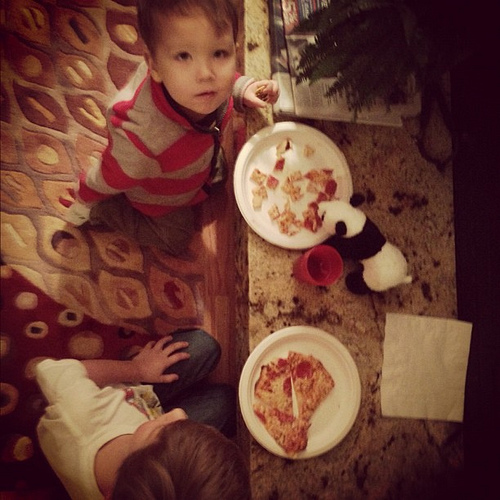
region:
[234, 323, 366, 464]
Pizza on a plate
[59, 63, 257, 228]
A sweater is gray and red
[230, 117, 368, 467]
Two plates on a table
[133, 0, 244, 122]
Brown hair on boy's head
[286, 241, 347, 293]
Red cup on the table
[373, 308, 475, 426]
A napkin is square shaped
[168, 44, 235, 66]
A pair of eyes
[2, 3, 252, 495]
Two boys are sitting on a rug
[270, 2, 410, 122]
newspapers on the counter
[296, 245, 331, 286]
a red cup on the counter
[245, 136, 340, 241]
a plate of food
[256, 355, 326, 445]
pizza on a plate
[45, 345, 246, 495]
a boy with a white shirt on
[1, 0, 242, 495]
the red carpet under the boys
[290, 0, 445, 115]
a plant on the counter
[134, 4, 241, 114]
a boy with brown light hair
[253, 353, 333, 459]
pizza slices in a white plate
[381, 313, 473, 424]
a white sheet of paper towel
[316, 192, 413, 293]
a panda plushie eating bits of pizza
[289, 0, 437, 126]
green leaves of a plant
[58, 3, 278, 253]
a boy sitting on a carpet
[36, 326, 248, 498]
a girl sitting on a carpet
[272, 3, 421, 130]
folded newspapers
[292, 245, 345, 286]
a red plastic glass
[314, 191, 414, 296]
a black and white panda plushie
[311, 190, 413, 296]
a small black and white stuffed panda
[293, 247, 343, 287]
a small red plastic cup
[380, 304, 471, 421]
a white napkin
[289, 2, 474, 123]
a house plant on table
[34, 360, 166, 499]
a white short sleeve shirt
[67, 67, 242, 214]
a gray and red article of clothing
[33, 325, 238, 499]
a boy in blue jeans sitting on floor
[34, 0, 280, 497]
two boys sitting on floor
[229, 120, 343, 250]
round white plate with stuffed panda near it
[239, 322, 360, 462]
a round white plate with pizza on it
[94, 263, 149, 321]
leaf design on carpet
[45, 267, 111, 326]
leaf design on carpet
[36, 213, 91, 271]
leaf design on carpet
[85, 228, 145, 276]
leaf design on carpet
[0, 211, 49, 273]
leaf design on carpet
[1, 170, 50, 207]
leaf design on carpet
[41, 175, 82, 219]
leaf design on carpet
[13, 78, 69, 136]
leaf design on carpet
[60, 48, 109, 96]
leaf design on carpet